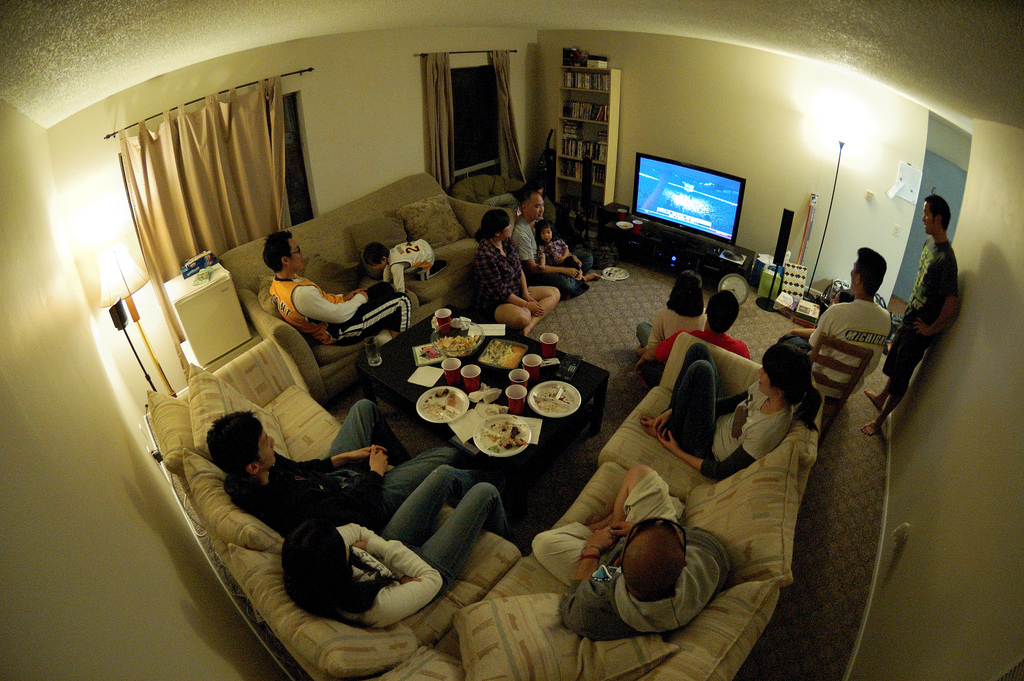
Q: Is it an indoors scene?
A: Yes, it is indoors.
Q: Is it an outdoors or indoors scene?
A: It is indoors.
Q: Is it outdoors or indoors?
A: It is indoors.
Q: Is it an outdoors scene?
A: No, it is indoors.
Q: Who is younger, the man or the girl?
A: The girl is younger than the man.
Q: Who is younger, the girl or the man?
A: The girl is younger than the man.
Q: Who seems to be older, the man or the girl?
A: The man is older than the girl.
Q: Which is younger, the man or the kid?
A: The kid is younger than the man.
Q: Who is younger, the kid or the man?
A: The kid is younger than the man.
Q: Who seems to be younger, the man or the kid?
A: The kid is younger than the man.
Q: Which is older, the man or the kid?
A: The man is older than the kid.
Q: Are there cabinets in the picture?
A: No, there are no cabinets.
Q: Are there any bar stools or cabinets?
A: No, there are no cabinets or bar stools.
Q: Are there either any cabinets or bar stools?
A: No, there are no cabinets or bar stools.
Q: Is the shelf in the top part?
A: Yes, the shelf is in the top of the image.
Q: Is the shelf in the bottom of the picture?
A: No, the shelf is in the top of the image.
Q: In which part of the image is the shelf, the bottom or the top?
A: The shelf is in the top of the image.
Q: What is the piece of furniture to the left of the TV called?
A: The piece of furniture is a shelf.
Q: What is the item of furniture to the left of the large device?
A: The piece of furniture is a shelf.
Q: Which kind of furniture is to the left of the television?
A: The piece of furniture is a shelf.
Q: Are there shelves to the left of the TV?
A: Yes, there is a shelf to the left of the TV.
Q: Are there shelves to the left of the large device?
A: Yes, there is a shelf to the left of the TV.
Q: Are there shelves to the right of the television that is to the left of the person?
A: No, the shelf is to the left of the television.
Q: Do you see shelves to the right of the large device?
A: No, the shelf is to the left of the television.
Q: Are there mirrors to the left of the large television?
A: No, there is a shelf to the left of the television.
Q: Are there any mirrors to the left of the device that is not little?
A: No, there is a shelf to the left of the television.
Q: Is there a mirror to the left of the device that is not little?
A: No, there is a shelf to the left of the television.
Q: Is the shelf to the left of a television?
A: Yes, the shelf is to the left of a television.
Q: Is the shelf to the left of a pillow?
A: No, the shelf is to the left of a television.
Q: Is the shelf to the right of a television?
A: No, the shelf is to the left of a television.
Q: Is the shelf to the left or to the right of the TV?
A: The shelf is to the left of the TV.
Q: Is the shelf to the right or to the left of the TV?
A: The shelf is to the left of the TV.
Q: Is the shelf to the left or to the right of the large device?
A: The shelf is to the left of the TV.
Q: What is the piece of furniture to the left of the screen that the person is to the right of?
A: The piece of furniture is a shelf.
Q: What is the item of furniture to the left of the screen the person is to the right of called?
A: The piece of furniture is a shelf.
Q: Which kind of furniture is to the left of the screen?
A: The piece of furniture is a shelf.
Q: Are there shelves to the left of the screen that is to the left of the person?
A: Yes, there is a shelf to the left of the screen.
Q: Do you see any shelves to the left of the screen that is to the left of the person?
A: Yes, there is a shelf to the left of the screen.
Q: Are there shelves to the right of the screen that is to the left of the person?
A: No, the shelf is to the left of the screen.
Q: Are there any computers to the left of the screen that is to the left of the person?
A: No, there is a shelf to the left of the screen.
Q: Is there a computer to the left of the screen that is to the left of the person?
A: No, there is a shelf to the left of the screen.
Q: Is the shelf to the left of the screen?
A: Yes, the shelf is to the left of the screen.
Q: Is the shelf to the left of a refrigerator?
A: No, the shelf is to the left of the screen.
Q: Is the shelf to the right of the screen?
A: No, the shelf is to the left of the screen.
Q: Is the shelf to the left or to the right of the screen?
A: The shelf is to the left of the screen.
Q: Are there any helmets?
A: No, there are no helmets.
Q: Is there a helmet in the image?
A: No, there are no helmets.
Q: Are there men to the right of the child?
A: Yes, there is a man to the right of the child.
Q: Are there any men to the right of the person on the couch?
A: Yes, there is a man to the right of the child.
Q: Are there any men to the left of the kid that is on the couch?
A: No, the man is to the right of the kid.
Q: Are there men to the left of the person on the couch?
A: No, the man is to the right of the kid.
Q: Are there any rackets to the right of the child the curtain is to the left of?
A: No, there is a man to the right of the kid.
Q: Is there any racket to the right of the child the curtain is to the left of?
A: No, there is a man to the right of the kid.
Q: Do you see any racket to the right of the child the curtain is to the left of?
A: No, there is a man to the right of the kid.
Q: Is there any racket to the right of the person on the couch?
A: No, there is a man to the right of the kid.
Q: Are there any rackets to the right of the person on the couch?
A: No, there is a man to the right of the kid.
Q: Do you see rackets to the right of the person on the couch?
A: No, there is a man to the right of the kid.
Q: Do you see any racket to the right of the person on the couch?
A: No, there is a man to the right of the kid.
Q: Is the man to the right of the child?
A: Yes, the man is to the right of the child.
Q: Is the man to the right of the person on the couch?
A: Yes, the man is to the right of the child.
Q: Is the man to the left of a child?
A: No, the man is to the right of a child.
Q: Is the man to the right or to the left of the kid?
A: The man is to the right of the kid.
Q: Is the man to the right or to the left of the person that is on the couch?
A: The man is to the right of the kid.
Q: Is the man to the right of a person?
A: No, the man is to the left of a person.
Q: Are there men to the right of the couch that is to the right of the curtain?
A: Yes, there is a man to the right of the couch.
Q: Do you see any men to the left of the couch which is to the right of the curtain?
A: No, the man is to the right of the couch.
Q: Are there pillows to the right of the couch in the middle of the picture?
A: No, there is a man to the right of the couch.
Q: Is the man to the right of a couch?
A: Yes, the man is to the right of a couch.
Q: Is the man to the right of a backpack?
A: No, the man is to the right of a couch.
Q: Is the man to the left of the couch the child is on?
A: No, the man is to the right of the couch.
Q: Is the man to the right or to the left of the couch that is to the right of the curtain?
A: The man is to the right of the couch.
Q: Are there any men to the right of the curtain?
A: Yes, there is a man to the right of the curtain.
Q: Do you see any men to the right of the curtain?
A: Yes, there is a man to the right of the curtain.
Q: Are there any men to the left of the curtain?
A: No, the man is to the right of the curtain.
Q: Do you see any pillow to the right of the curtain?
A: No, there is a man to the right of the curtain.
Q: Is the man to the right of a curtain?
A: Yes, the man is to the right of a curtain.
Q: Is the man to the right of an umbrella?
A: No, the man is to the right of a curtain.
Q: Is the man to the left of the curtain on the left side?
A: No, the man is to the right of the curtain.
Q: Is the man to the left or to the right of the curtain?
A: The man is to the right of the curtain.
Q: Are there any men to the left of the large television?
A: Yes, there is a man to the left of the TV.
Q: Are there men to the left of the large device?
A: Yes, there is a man to the left of the TV.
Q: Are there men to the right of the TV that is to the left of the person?
A: No, the man is to the left of the TV.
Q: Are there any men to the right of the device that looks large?
A: No, the man is to the left of the TV.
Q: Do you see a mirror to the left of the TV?
A: No, there is a man to the left of the TV.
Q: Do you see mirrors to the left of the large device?
A: No, there is a man to the left of the TV.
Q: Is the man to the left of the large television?
A: Yes, the man is to the left of the TV.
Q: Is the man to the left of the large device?
A: Yes, the man is to the left of the TV.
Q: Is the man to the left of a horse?
A: No, the man is to the left of the TV.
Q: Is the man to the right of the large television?
A: No, the man is to the left of the TV.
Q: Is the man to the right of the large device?
A: No, the man is to the left of the TV.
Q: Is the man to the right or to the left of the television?
A: The man is to the left of the television.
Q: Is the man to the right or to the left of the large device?
A: The man is to the left of the television.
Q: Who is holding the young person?
A: The man is holding the girl.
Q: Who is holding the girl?
A: The man is holding the girl.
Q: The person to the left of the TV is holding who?
A: The man is holding the girl.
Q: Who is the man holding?
A: The man is holding the girl.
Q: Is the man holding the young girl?
A: Yes, the man is holding the girl.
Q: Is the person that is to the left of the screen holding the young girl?
A: Yes, the man is holding the girl.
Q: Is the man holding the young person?
A: Yes, the man is holding the girl.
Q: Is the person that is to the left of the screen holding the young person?
A: Yes, the man is holding the girl.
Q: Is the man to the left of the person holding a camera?
A: No, the man is holding the girl.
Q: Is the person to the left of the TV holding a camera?
A: No, the man is holding the girl.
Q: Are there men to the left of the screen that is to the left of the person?
A: Yes, there is a man to the left of the screen.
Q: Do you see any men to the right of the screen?
A: No, the man is to the left of the screen.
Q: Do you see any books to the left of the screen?
A: No, there is a man to the left of the screen.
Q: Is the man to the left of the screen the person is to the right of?
A: Yes, the man is to the left of the screen.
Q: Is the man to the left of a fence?
A: No, the man is to the left of the screen.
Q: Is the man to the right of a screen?
A: No, the man is to the left of a screen.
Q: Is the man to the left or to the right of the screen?
A: The man is to the left of the screen.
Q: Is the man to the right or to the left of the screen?
A: The man is to the left of the screen.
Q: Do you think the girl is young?
A: Yes, the girl is young.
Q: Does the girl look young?
A: Yes, the girl is young.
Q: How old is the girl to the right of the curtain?
A: The girl is young.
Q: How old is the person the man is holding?
A: The girl is young.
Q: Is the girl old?
A: No, the girl is young.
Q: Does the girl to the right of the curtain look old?
A: No, the girl is young.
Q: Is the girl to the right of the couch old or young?
A: The girl is young.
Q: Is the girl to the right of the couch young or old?
A: The girl is young.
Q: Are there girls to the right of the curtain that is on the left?
A: Yes, there is a girl to the right of the curtain.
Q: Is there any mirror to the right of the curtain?
A: No, there is a girl to the right of the curtain.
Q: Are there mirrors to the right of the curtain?
A: No, there is a girl to the right of the curtain.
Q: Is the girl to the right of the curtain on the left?
A: Yes, the girl is to the right of the curtain.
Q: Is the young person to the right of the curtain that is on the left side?
A: Yes, the girl is to the right of the curtain.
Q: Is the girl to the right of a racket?
A: No, the girl is to the right of the curtain.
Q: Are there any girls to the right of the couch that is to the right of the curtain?
A: Yes, there is a girl to the right of the couch.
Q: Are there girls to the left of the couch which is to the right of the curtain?
A: No, the girl is to the right of the couch.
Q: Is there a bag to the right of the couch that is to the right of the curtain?
A: No, there is a girl to the right of the couch.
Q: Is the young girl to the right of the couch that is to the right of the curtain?
A: Yes, the girl is to the right of the couch.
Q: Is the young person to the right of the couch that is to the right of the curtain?
A: Yes, the girl is to the right of the couch.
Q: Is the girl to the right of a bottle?
A: No, the girl is to the right of the couch.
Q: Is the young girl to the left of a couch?
A: No, the girl is to the right of a couch.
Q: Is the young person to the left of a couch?
A: No, the girl is to the right of a couch.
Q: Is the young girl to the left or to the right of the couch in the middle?
A: The girl is to the right of the couch.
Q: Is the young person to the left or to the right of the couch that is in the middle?
A: The girl is to the right of the couch.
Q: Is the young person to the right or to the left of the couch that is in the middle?
A: The girl is to the right of the couch.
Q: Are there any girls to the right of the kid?
A: Yes, there is a girl to the right of the kid.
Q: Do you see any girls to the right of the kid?
A: Yes, there is a girl to the right of the kid.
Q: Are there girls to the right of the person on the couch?
A: Yes, there is a girl to the right of the kid.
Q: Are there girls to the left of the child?
A: No, the girl is to the right of the child.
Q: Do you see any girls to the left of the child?
A: No, the girl is to the right of the child.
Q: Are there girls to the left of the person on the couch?
A: No, the girl is to the right of the child.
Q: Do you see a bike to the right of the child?
A: No, there is a girl to the right of the child.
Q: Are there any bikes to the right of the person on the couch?
A: No, there is a girl to the right of the child.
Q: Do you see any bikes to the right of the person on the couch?
A: No, there is a girl to the right of the child.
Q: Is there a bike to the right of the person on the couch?
A: No, there is a girl to the right of the child.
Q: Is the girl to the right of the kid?
A: Yes, the girl is to the right of the kid.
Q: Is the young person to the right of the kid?
A: Yes, the girl is to the right of the kid.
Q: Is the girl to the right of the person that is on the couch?
A: Yes, the girl is to the right of the kid.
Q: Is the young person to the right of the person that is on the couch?
A: Yes, the girl is to the right of the kid.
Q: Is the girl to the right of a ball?
A: No, the girl is to the right of the kid.